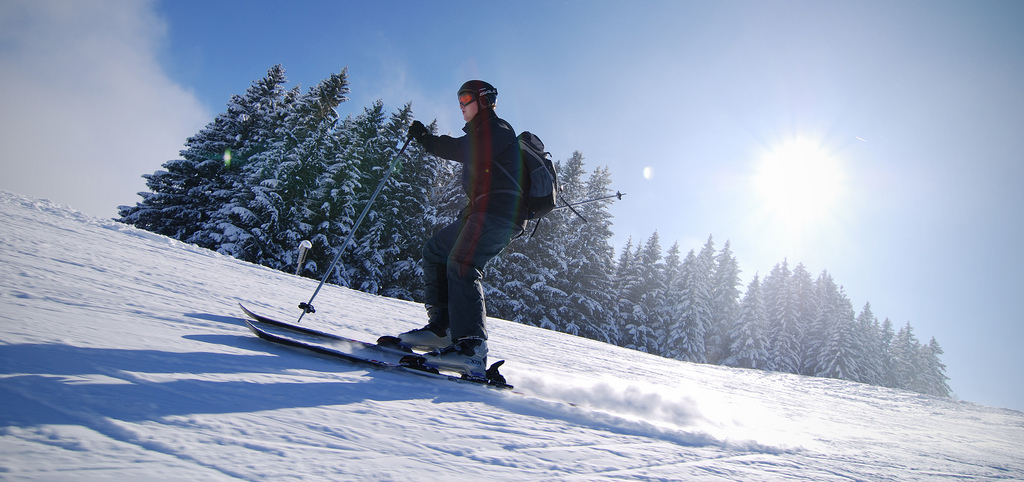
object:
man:
[401, 80, 526, 381]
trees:
[113, 64, 948, 399]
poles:
[295, 120, 424, 323]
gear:
[425, 115, 554, 337]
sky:
[0, 0, 1024, 409]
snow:
[0, 193, 1024, 479]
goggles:
[458, 91, 477, 106]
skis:
[238, 303, 514, 388]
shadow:
[0, 313, 485, 428]